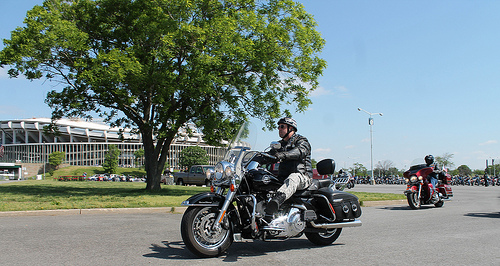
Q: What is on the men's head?
A: Helmets.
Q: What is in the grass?
A: Tree.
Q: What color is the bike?
A: Black.